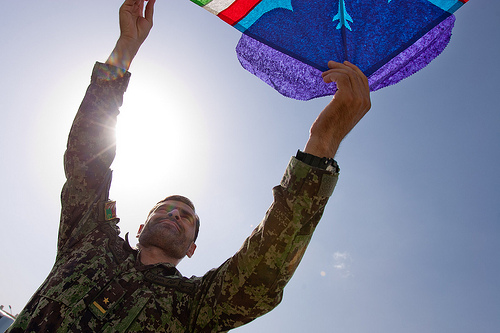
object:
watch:
[294, 148, 341, 177]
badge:
[103, 199, 117, 221]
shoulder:
[108, 226, 136, 260]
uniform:
[6, 60, 341, 333]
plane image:
[332, 0, 354, 31]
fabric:
[188, 0, 472, 101]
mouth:
[155, 220, 183, 234]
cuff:
[278, 156, 339, 200]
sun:
[44, 74, 202, 196]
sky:
[0, 0, 499, 332]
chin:
[145, 229, 175, 247]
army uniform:
[6, 60, 340, 332]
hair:
[147, 195, 201, 243]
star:
[102, 297, 108, 304]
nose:
[166, 208, 183, 222]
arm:
[60, 45, 144, 230]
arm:
[190, 140, 340, 333]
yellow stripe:
[90, 300, 108, 314]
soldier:
[9, 5, 381, 330]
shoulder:
[176, 270, 211, 289]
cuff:
[86, 61, 133, 94]